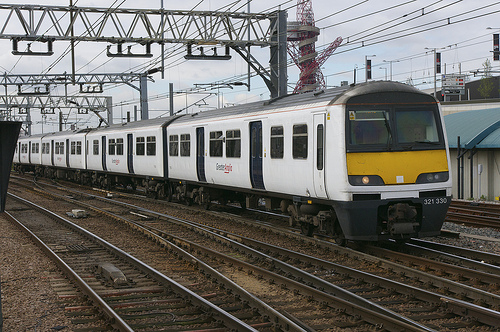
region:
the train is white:
[142, 65, 355, 245]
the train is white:
[120, 40, 393, 325]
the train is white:
[136, 116, 318, 323]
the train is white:
[97, 71, 309, 183]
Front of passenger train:
[325, 73, 460, 221]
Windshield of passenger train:
[335, 95, 451, 155]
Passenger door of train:
[236, 110, 262, 210]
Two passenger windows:
[256, 115, 311, 165]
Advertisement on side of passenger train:
[205, 155, 245, 177]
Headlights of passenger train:
[355, 162, 453, 188]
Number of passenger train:
[412, 185, 464, 220]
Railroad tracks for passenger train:
[6, 165, 491, 325]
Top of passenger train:
[2, 75, 440, 137]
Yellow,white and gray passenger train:
[6, 75, 458, 247]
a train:
[294, 74, 496, 228]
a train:
[272, 20, 494, 298]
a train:
[220, 92, 462, 323]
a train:
[275, 90, 422, 274]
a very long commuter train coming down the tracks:
[24, 71, 479, 244]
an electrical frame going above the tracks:
[1, 4, 300, 106]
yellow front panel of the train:
[344, 148, 450, 187]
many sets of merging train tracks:
[24, 190, 317, 330]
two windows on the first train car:
[262, 121, 312, 168]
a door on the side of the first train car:
[244, 116, 269, 188]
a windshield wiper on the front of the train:
[373, 108, 398, 149]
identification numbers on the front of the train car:
[420, 191, 450, 211]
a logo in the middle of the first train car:
[210, 161, 234, 178]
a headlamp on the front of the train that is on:
[352, 169, 379, 186]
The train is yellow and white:
[57, 88, 456, 240]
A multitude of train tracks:
[48, 187, 468, 328]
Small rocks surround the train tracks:
[8, 196, 103, 318]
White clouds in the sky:
[340, 0, 451, 36]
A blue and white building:
[447, 110, 497, 196]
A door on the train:
[245, 121, 272, 186]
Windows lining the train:
[105, 129, 315, 165]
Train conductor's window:
[356, 111, 442, 157]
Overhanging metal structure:
[0, 0, 295, 85]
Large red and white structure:
[288, 10, 330, 90]